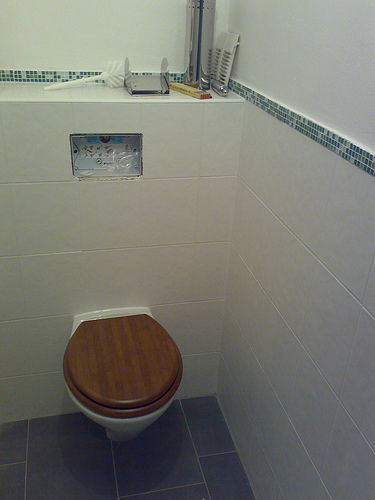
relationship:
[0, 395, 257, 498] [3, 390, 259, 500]
tile of floor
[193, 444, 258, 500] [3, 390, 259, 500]
tile of floor